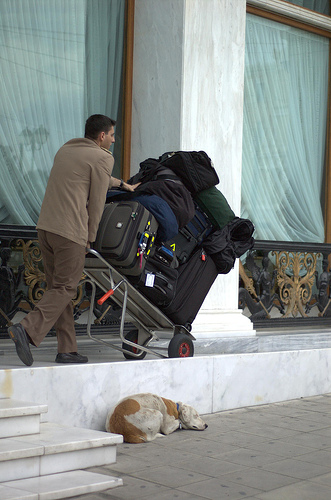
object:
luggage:
[97, 198, 159, 279]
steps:
[0, 396, 49, 434]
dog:
[104, 392, 207, 443]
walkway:
[63, 393, 330, 499]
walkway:
[0, 326, 330, 373]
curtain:
[0, 0, 128, 226]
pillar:
[129, 0, 257, 341]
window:
[242, 13, 329, 244]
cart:
[82, 249, 195, 361]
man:
[6, 113, 140, 367]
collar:
[174, 403, 184, 422]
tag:
[143, 271, 155, 289]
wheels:
[167, 333, 194, 357]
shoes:
[7, 320, 35, 366]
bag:
[193, 188, 235, 232]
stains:
[187, 472, 194, 481]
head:
[182, 404, 208, 433]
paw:
[177, 418, 186, 434]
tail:
[121, 424, 165, 442]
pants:
[19, 229, 92, 357]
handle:
[95, 281, 124, 306]